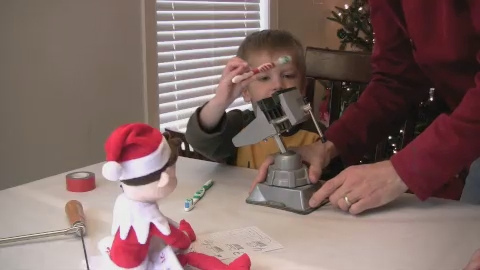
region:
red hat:
[85, 109, 170, 191]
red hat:
[71, 108, 216, 225]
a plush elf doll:
[95, 127, 249, 266]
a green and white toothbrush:
[178, 170, 222, 211]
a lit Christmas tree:
[323, 5, 447, 178]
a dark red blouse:
[315, 0, 478, 195]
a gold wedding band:
[341, 190, 355, 207]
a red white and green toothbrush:
[233, 48, 289, 82]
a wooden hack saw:
[5, 196, 90, 265]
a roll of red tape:
[63, 168, 98, 197]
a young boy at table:
[188, 28, 325, 175]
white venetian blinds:
[153, 0, 266, 137]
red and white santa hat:
[100, 119, 163, 180]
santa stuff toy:
[86, 102, 188, 267]